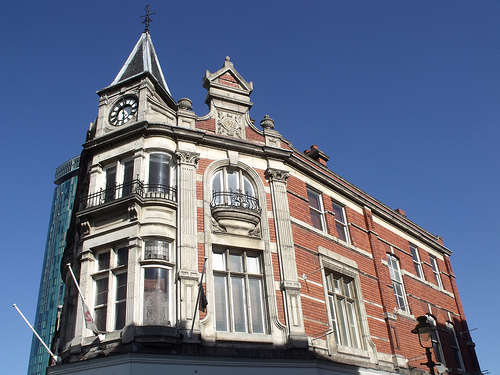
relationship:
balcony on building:
[213, 191, 263, 234] [46, 4, 483, 374]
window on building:
[310, 210, 323, 233] [46, 4, 483, 374]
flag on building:
[199, 285, 209, 312] [46, 4, 483, 374]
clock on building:
[109, 94, 139, 127] [46, 4, 483, 374]